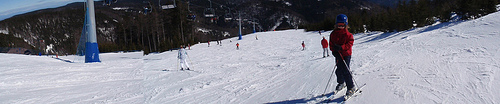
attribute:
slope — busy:
[0, 6, 499, 102]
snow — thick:
[4, 8, 498, 102]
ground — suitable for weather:
[423, 67, 450, 82]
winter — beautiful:
[76, 3, 450, 96]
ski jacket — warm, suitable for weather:
[329, 29, 356, 63]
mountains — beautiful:
[0, 0, 498, 64]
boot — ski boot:
[343, 81, 358, 99]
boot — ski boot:
[331, 77, 346, 93]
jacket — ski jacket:
[327, 21, 354, 59]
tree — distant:
[117, 15, 131, 54]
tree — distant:
[152, 2, 164, 51]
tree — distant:
[172, 8, 185, 48]